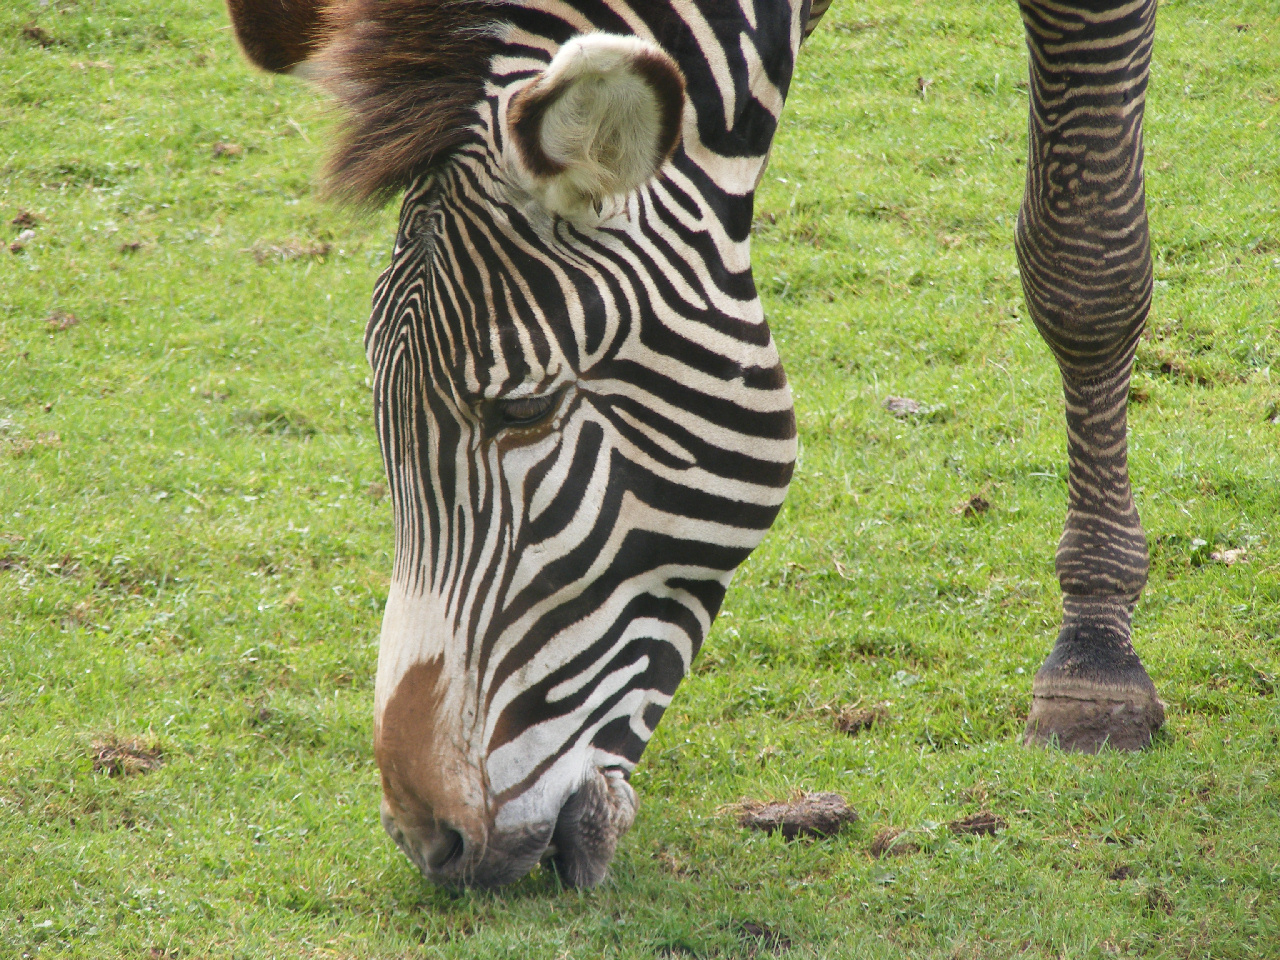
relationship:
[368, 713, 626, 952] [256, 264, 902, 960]
mouth of zebra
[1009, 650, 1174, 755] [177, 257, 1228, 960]
hoof of a zebra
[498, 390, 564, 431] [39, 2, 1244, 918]
eye of zebra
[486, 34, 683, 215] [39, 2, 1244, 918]
ear of zebra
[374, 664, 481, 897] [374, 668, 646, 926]
nose on nose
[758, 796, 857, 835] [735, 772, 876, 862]
grass of grass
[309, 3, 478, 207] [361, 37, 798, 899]
mane on zebra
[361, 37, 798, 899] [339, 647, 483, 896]
zebra has nose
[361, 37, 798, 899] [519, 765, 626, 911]
zebra has mouth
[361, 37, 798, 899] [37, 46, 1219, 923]
zebra eating grass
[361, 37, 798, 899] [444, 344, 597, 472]
zebra has eye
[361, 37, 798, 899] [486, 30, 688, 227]
zebra has ear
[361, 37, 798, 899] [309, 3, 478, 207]
zebra has mane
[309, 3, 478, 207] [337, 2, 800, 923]
mane on head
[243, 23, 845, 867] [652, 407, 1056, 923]
zebra in grass